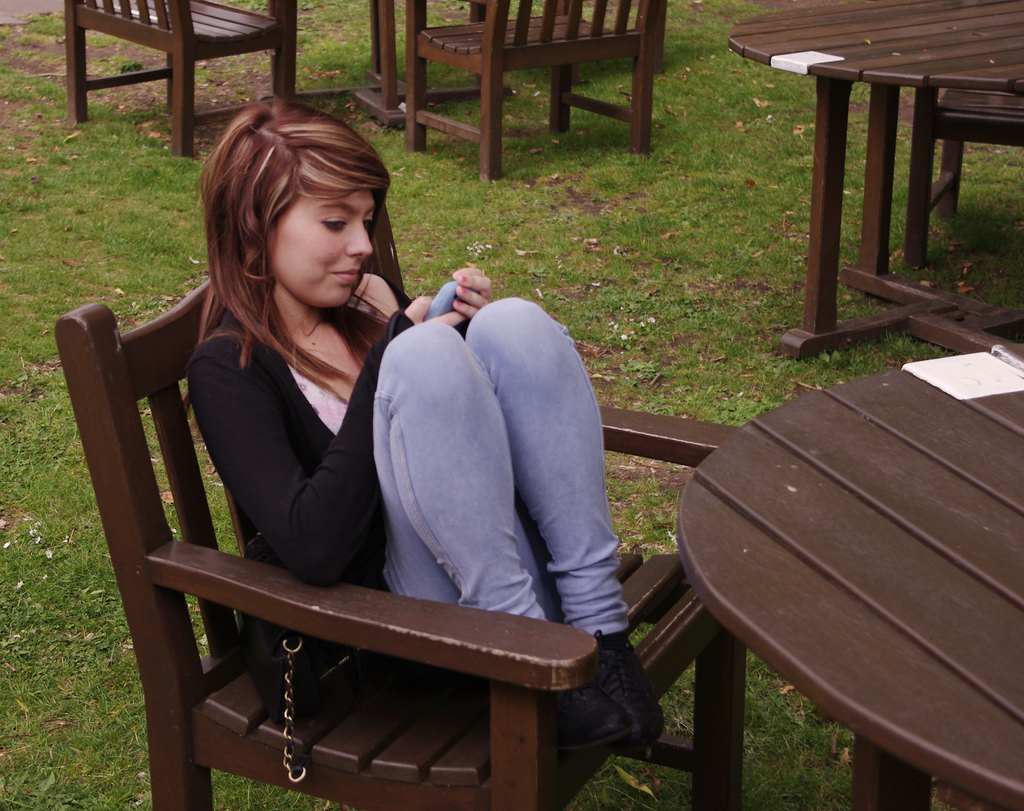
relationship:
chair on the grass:
[124, 385, 179, 787] [47, 621, 100, 781]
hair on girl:
[177, 85, 456, 408] [186, 96, 675, 762]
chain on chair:
[270, 623, 314, 792] [49, 236, 752, 807]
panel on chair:
[146, 366, 248, 660] [49, 236, 752, 807]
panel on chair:
[371, 541, 646, 805] [51, 165, 754, 805]